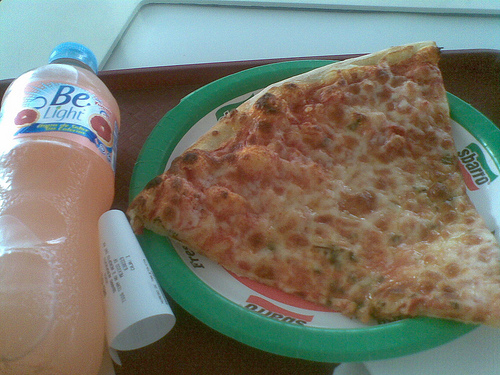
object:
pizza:
[124, 41, 500, 326]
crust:
[121, 41, 440, 216]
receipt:
[98, 208, 177, 352]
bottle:
[0, 41, 121, 375]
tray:
[0, 48, 499, 375]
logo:
[241, 294, 314, 328]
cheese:
[124, 40, 500, 328]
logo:
[457, 142, 499, 191]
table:
[0, 0, 500, 80]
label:
[12, 85, 91, 122]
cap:
[49, 41, 96, 63]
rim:
[128, 58, 342, 204]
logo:
[41, 84, 92, 125]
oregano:
[389, 232, 401, 248]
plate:
[127, 59, 500, 364]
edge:
[203, 322, 398, 360]